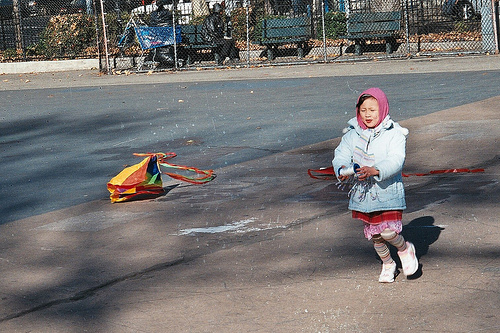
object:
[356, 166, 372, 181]
hands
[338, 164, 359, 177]
spool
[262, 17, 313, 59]
bench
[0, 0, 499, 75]
fence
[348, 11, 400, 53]
bench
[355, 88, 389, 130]
head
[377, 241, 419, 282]
pair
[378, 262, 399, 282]
shoes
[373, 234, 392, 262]
leggings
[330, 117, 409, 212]
coat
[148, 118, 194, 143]
leaves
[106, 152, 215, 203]
kite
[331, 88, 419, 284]
child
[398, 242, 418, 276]
sneakers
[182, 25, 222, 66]
bench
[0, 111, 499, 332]
shadows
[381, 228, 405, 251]
stocking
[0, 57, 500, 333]
road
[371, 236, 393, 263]
socks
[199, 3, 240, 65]
person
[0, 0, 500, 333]
park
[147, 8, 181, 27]
garbage bag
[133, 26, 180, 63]
cart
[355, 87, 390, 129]
cap